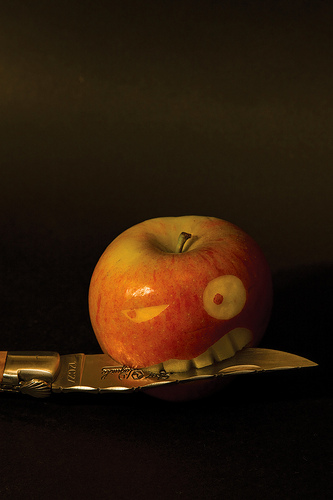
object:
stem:
[174, 230, 190, 254]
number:
[66, 361, 76, 384]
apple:
[88, 215, 272, 377]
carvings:
[100, 363, 175, 386]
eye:
[201, 274, 249, 322]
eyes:
[120, 304, 171, 324]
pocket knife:
[1, 343, 318, 396]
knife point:
[286, 349, 319, 369]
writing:
[66, 361, 77, 385]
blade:
[6, 346, 321, 395]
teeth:
[123, 328, 264, 375]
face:
[105, 266, 264, 377]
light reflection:
[127, 285, 157, 298]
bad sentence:
[143, 328, 254, 376]